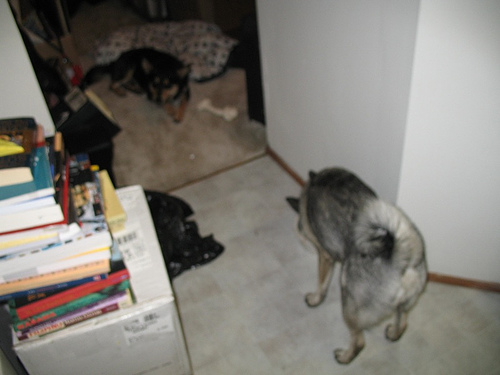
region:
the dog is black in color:
[143, 47, 181, 80]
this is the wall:
[383, 17, 474, 141]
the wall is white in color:
[326, 39, 402, 122]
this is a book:
[23, 187, 55, 225]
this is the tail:
[377, 198, 429, 273]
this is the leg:
[330, 299, 382, 374]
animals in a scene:
[4, 20, 480, 349]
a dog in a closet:
[74, 48, 234, 135]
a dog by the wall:
[251, 155, 453, 367]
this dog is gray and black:
[273, 175, 429, 355]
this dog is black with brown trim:
[90, 45, 205, 117]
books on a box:
[14, 133, 154, 325]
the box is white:
[63, 235, 208, 371]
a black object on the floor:
[145, 187, 224, 279]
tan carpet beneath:
[133, 112, 228, 155]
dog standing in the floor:
[268, 160, 440, 367]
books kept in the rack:
[0, 105, 163, 347]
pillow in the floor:
[96, 21, 227, 85]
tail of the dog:
[366, 199, 423, 271]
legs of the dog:
[304, 274, 364, 368]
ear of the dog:
[281, 191, 304, 214]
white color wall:
[293, 47, 425, 120]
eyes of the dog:
[146, 75, 171, 88]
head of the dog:
[143, 65, 180, 108]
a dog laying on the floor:
[91, 16, 226, 138]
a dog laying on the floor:
[92, 61, 206, 181]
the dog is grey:
[272, 169, 473, 372]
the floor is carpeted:
[118, 125, 218, 167]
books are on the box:
[10, 109, 136, 324]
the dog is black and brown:
[113, 34, 199, 130]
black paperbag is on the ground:
[151, 182, 225, 275]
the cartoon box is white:
[121, 189, 203, 374]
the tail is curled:
[353, 204, 414, 250]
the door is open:
[21, 16, 318, 176]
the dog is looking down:
[266, 165, 455, 359]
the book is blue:
[12, 182, 57, 201]